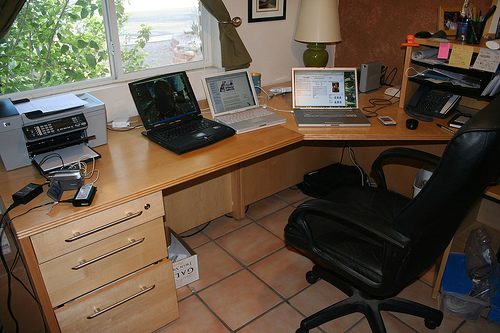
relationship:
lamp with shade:
[289, 0, 344, 72] [287, 2, 349, 50]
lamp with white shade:
[293, 0, 341, 69] [292, 0, 341, 45]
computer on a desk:
[284, 66, 371, 131] [1, 77, 451, 331]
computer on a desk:
[204, 69, 285, 130] [1, 77, 451, 331]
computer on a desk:
[132, 71, 236, 156] [1, 77, 451, 331]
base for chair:
[292, 262, 447, 332] [277, 94, 499, 330]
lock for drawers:
[141, 202, 156, 212] [26, 184, 184, 331]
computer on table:
[291, 66, 373, 127] [212, 60, 447, 161]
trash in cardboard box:
[165, 228, 187, 261] [163, 227, 199, 297]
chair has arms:
[214, 80, 481, 332] [248, 184, 415, 253]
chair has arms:
[214, 80, 481, 332] [339, 134, 474, 175]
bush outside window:
[13, 55, 111, 91] [1, 0, 116, 100]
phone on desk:
[404, 85, 463, 122] [405, 78, 461, 118]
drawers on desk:
[37, 189, 172, 331] [9, 67, 426, 320]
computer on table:
[128, 71, 237, 156] [8, 116, 496, 263]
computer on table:
[201, 69, 287, 134] [8, 116, 496, 263]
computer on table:
[291, 66, 373, 127] [8, 116, 496, 263]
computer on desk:
[128, 71, 237, 156] [1, 88, 497, 323]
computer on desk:
[201, 69, 287, 134] [1, 77, 451, 331]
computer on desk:
[291, 66, 373, 127] [35, 114, 308, 208]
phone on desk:
[411, 74, 464, 127] [1, 77, 451, 331]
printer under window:
[1, 91, 117, 174] [6, 4, 186, 90]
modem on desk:
[359, 59, 384, 93] [1, 77, 451, 331]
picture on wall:
[244, 0, 287, 23] [2, 0, 339, 150]